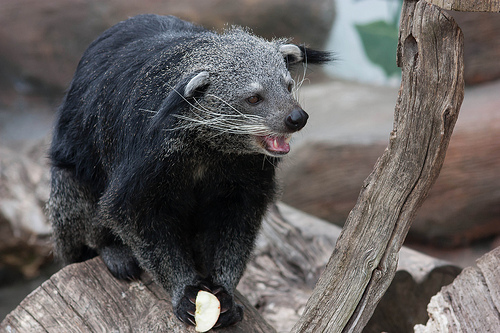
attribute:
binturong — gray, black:
[47, 12, 335, 329]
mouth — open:
[254, 131, 294, 156]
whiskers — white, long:
[135, 82, 272, 140]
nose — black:
[285, 109, 309, 130]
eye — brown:
[247, 93, 262, 107]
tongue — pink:
[265, 135, 289, 152]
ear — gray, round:
[183, 70, 209, 99]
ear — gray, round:
[278, 44, 302, 63]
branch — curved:
[285, 2, 499, 330]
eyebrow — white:
[241, 82, 265, 95]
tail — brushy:
[48, 165, 96, 263]